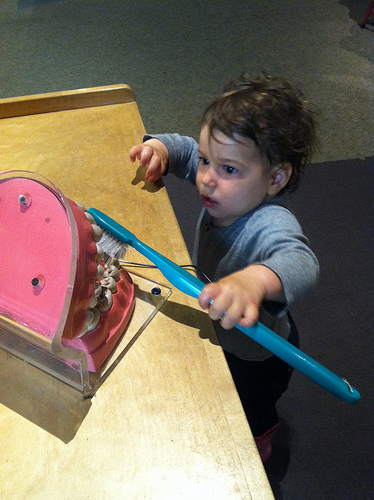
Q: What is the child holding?
A: A toothbrush.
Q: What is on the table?
A: A set of teeth.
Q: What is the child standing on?
A: A mat.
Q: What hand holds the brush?
A: Left hand.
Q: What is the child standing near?
A: A table.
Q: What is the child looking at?
A: The set of teeth.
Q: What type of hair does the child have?
A: Curly.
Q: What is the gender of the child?
A: Male.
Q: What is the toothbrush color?
A: Blue.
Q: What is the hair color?
A: Brown.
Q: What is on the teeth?
A: Gums.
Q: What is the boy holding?
A: Toothbrush.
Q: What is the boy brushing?
A: Teeth.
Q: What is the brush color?
A: Blue.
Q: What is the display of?
A: Teeth.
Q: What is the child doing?
A: Brushing teeth.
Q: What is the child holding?
A: A giant toothbrush.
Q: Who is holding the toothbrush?
A: The child.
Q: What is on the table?
A: Giant teeth.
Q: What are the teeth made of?
A: Plastic.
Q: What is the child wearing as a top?
A: A gray sweater.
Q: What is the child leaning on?
A: The table.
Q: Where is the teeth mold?
A: On the table.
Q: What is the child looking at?
A: Teeth.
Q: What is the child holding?
A: Giant toothbrush.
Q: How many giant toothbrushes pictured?
A: 1.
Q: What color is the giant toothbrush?
A: Blue.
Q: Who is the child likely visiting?
A: Dentist.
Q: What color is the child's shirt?
A: Grey.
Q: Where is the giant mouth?
A: On a table.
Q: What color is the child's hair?
A: Brown.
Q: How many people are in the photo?
A: 1.